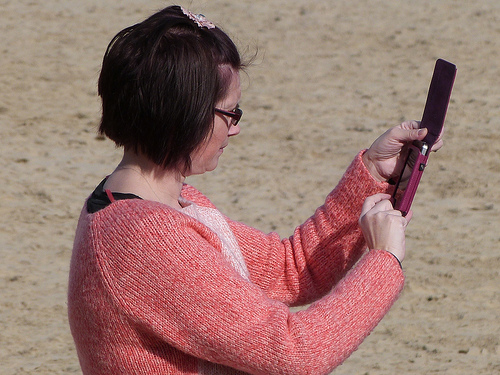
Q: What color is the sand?
A: Brown.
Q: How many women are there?
A: One.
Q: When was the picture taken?
A: Daytime.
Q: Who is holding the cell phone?
A: The woman.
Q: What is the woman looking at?
A: The cell phone.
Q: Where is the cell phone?
A: In the woman's hands.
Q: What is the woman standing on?
A: Sand.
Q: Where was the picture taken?
A: On the beach.